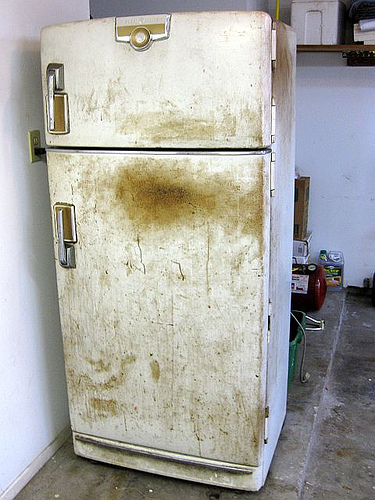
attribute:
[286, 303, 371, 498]
floor — concrete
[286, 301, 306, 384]
basket — green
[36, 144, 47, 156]
power cord — black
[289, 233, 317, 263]
box — cardboard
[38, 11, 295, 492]
refrigerator — white, top of, Old, lower, part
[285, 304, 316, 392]
basket — green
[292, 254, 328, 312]
tank — red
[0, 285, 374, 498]
ground — gray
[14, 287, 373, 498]
concrete ground — dirty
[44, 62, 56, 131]
handle — metal, latch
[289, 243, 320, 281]
pump — part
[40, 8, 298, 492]
fridge — dirty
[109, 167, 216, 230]
brown spot — big